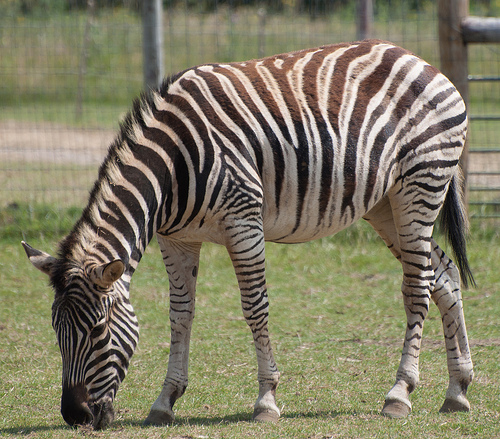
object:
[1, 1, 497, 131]
grass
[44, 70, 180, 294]
hair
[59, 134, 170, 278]
neck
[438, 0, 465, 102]
post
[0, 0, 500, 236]
fence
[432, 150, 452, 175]
ground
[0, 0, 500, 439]
zoo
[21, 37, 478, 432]
zebra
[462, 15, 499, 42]
top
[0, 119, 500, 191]
road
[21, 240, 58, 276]
ear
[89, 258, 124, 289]
ear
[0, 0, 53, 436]
fenced area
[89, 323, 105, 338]
left eye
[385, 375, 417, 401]
back hoove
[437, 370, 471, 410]
back hoove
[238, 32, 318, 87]
ground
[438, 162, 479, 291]
tail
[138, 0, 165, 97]
poles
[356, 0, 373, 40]
poles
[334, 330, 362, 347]
dirt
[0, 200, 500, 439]
grass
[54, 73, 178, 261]
mane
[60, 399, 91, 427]
nose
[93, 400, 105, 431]
mouth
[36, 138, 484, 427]
sunshine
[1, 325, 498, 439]
ground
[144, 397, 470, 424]
hooves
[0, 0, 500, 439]
enclosure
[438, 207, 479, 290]
haired tail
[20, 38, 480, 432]
grazing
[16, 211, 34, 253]
rails